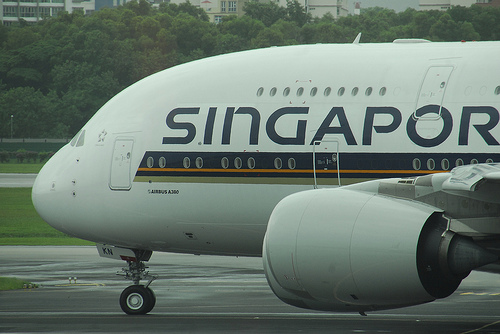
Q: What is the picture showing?
A: It is showing a forest.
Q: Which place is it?
A: It is a forest.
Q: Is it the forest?
A: Yes, it is the forest.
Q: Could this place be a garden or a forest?
A: It is a forest.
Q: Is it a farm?
A: No, it is a forest.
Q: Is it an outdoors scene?
A: Yes, it is outdoors.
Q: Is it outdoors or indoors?
A: It is outdoors.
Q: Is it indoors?
A: No, it is outdoors.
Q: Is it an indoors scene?
A: No, it is outdoors.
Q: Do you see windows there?
A: Yes, there are windows.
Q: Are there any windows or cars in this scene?
A: Yes, there are windows.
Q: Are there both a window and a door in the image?
A: Yes, there are both a window and a door.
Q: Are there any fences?
A: No, there are no fences.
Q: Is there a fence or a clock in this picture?
A: No, there are no fences or clocks.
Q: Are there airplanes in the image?
A: Yes, there is an airplane.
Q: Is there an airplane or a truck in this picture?
A: Yes, there is an airplane.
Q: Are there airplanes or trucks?
A: Yes, there is an airplane.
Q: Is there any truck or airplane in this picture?
A: Yes, there is an airplane.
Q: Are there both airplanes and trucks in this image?
A: No, there is an airplane but no trucks.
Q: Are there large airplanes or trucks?
A: Yes, there is a large airplane.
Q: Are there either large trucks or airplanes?
A: Yes, there is a large airplane.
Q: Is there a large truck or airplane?
A: Yes, there is a large airplane.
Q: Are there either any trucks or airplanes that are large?
A: Yes, the airplane is large.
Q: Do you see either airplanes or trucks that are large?
A: Yes, the airplane is large.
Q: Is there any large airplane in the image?
A: Yes, there is a large airplane.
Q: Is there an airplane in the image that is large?
A: Yes, there is an airplane that is large.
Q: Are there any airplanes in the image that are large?
A: Yes, there is an airplane that is large.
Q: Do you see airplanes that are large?
A: Yes, there is an airplane that is large.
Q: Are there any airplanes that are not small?
A: Yes, there is a large airplane.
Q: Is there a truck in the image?
A: No, there are no trucks.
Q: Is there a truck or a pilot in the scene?
A: No, there are no trucks or pilots.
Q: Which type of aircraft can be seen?
A: The aircraft is an airplane.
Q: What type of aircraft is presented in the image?
A: The aircraft is an airplane.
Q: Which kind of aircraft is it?
A: The aircraft is an airplane.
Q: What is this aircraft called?
A: That is an airplane.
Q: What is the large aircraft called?
A: The aircraft is an airplane.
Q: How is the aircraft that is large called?
A: The aircraft is an airplane.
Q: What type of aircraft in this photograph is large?
A: The aircraft is an airplane.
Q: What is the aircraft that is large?
A: The aircraft is an airplane.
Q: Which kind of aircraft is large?
A: The aircraft is an airplane.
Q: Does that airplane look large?
A: Yes, the airplane is large.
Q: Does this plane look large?
A: Yes, the plane is large.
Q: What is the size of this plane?
A: The plane is large.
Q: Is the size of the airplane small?
A: No, the airplane is large.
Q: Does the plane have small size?
A: No, the plane is large.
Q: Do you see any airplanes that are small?
A: No, there is an airplane but it is large.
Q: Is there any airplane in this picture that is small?
A: No, there is an airplane but it is large.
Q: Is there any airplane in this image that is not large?
A: No, there is an airplane but it is large.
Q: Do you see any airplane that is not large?
A: No, there is an airplane but it is large.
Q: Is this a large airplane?
A: Yes, this is a large airplane.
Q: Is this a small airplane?
A: No, this is a large airplane.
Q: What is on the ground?
A: The airplane is on the ground.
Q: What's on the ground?
A: The airplane is on the ground.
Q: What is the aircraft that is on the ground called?
A: The aircraft is an airplane.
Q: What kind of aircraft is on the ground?
A: The aircraft is an airplane.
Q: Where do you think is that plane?
A: The plane is on the ground.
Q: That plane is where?
A: The plane is on the ground.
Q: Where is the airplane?
A: The plane is on the ground.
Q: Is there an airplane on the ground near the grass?
A: Yes, there is an airplane on the ground.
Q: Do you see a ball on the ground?
A: No, there is an airplane on the ground.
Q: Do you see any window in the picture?
A: Yes, there are windows.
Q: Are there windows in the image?
A: Yes, there are windows.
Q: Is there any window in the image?
A: Yes, there are windows.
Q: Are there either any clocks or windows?
A: Yes, there are windows.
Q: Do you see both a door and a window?
A: Yes, there are both a window and a door.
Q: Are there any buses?
A: No, there are no buses.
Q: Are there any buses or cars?
A: No, there are no buses or cars.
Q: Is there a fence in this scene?
A: No, there are no fences.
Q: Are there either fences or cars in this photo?
A: No, there are no fences or cars.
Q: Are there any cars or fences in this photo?
A: No, there are no fences or cars.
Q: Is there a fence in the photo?
A: No, there are no fences.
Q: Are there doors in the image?
A: Yes, there is a door.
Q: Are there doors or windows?
A: Yes, there is a door.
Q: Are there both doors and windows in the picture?
A: Yes, there are both a door and windows.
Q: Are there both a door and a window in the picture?
A: Yes, there are both a door and a window.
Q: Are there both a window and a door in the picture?
A: Yes, there are both a door and a window.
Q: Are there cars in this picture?
A: No, there are no cars.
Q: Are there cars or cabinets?
A: No, there are no cars or cabinets.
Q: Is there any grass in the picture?
A: Yes, there is grass.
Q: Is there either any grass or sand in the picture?
A: Yes, there is grass.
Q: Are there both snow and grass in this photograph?
A: No, there is grass but no snow.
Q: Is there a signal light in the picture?
A: No, there are no traffic lights.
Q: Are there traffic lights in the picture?
A: No, there are no traffic lights.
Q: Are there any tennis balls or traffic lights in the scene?
A: No, there are no traffic lights or tennis balls.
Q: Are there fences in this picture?
A: No, there are no fences.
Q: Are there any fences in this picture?
A: No, there are no fences.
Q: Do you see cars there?
A: No, there are no cars.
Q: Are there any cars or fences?
A: No, there are no cars or fences.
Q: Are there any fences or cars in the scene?
A: No, there are no cars or fences.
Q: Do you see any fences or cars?
A: No, there are no cars or fences.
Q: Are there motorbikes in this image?
A: No, there are no motorbikes.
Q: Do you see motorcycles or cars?
A: No, there are no motorcycles or cars.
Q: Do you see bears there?
A: No, there are no bears.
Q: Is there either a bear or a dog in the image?
A: No, there are no bears or dogs.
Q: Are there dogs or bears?
A: No, there are no bears or dogs.